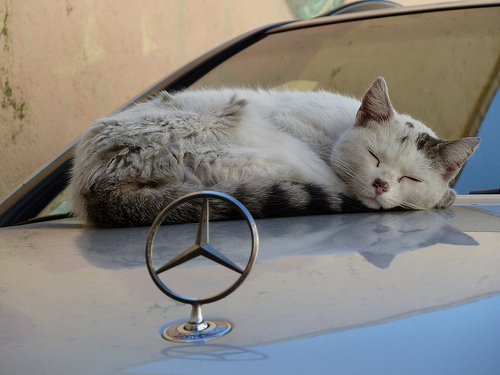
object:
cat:
[72, 76, 482, 224]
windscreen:
[16, 9, 496, 216]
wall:
[3, 2, 290, 210]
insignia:
[144, 183, 266, 307]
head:
[326, 72, 465, 208]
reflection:
[89, 216, 484, 271]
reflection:
[165, 340, 280, 373]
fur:
[159, 93, 243, 111]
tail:
[105, 185, 250, 219]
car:
[0, 0, 493, 374]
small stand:
[176, 306, 212, 330]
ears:
[435, 109, 481, 162]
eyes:
[396, 155, 423, 187]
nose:
[372, 178, 393, 199]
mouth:
[360, 188, 391, 221]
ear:
[345, 67, 396, 117]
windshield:
[163, 7, 500, 140]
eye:
[358, 144, 387, 170]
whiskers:
[334, 155, 365, 183]